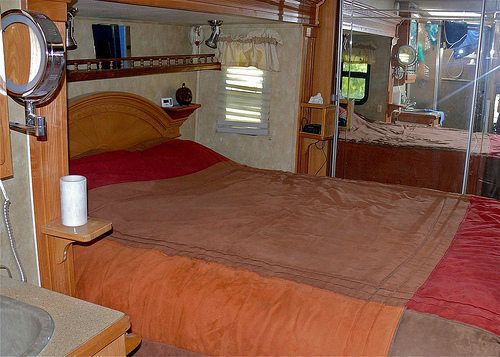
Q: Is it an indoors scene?
A: Yes, it is indoors.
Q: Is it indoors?
A: Yes, it is indoors.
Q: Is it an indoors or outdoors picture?
A: It is indoors.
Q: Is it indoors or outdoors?
A: It is indoors.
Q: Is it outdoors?
A: No, it is indoors.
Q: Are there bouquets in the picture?
A: No, there are no bouquets.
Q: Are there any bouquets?
A: No, there are no bouquets.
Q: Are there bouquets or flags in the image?
A: No, there are no bouquets or flags.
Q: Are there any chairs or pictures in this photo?
A: No, there are no chairs or pictures.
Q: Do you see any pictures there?
A: No, there are no pictures.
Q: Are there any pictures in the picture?
A: No, there are no pictures.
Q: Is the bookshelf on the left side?
A: Yes, the bookshelf is on the left of the image.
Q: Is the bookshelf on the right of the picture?
A: No, the bookshelf is on the left of the image.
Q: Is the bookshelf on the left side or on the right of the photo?
A: The bookshelf is on the left of the image.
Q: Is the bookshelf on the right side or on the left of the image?
A: The bookshelf is on the left of the image.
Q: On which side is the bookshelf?
A: The bookshelf is on the left of the image.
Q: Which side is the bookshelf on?
A: The bookshelf is on the left of the image.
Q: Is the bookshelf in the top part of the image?
A: Yes, the bookshelf is in the top of the image.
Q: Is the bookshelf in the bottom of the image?
A: No, the bookshelf is in the top of the image.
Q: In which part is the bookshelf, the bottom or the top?
A: The bookshelf is in the top of the image.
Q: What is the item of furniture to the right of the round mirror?
A: The piece of furniture is a bookshelf.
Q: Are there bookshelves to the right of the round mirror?
A: Yes, there is a bookshelf to the right of the mirror.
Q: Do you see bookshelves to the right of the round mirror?
A: Yes, there is a bookshelf to the right of the mirror.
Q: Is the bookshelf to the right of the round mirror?
A: Yes, the bookshelf is to the right of the mirror.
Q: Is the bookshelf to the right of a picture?
A: No, the bookshelf is to the right of the mirror.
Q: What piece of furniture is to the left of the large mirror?
A: The piece of furniture is a bookshelf.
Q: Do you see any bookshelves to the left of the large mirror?
A: Yes, there is a bookshelf to the left of the mirror.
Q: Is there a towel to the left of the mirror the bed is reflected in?
A: No, there is a bookshelf to the left of the mirror.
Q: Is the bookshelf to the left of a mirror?
A: Yes, the bookshelf is to the left of a mirror.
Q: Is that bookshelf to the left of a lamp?
A: No, the bookshelf is to the left of a mirror.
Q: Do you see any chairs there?
A: No, there are no chairs.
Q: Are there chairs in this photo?
A: No, there are no chairs.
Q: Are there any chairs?
A: No, there are no chairs.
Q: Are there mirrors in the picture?
A: Yes, there is a mirror.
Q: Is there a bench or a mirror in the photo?
A: Yes, there is a mirror.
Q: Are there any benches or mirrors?
A: Yes, there is a mirror.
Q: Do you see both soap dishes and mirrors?
A: No, there is a mirror but no soap dishes.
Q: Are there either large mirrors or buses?
A: Yes, there is a large mirror.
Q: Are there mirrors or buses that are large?
A: Yes, the mirror is large.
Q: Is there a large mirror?
A: Yes, there is a large mirror.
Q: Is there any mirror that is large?
A: Yes, there is a mirror that is large.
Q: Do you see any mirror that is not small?
A: Yes, there is a large mirror.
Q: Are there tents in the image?
A: No, there are no tents.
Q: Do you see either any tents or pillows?
A: No, there are no tents or pillows.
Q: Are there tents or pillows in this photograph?
A: No, there are no tents or pillows.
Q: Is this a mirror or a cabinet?
A: This is a mirror.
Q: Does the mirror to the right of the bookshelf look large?
A: Yes, the mirror is large.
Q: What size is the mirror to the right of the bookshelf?
A: The mirror is large.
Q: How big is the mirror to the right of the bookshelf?
A: The mirror is large.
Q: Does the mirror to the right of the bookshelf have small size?
A: No, the mirror is large.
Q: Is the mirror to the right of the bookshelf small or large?
A: The mirror is large.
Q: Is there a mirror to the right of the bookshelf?
A: Yes, there is a mirror to the right of the bookshelf.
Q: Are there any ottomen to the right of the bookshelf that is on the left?
A: No, there is a mirror to the right of the bookshelf.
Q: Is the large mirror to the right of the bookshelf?
A: Yes, the mirror is to the right of the bookshelf.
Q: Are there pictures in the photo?
A: No, there are no pictures.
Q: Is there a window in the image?
A: Yes, there is a window.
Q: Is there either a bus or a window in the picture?
A: Yes, there is a window.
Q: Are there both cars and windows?
A: No, there is a window but no cars.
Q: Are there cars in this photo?
A: No, there are no cars.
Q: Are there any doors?
A: Yes, there are doors.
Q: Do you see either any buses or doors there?
A: Yes, there are doors.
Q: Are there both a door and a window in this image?
A: Yes, there are both a door and a window.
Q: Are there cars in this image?
A: No, there are no cars.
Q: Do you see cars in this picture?
A: No, there are no cars.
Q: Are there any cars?
A: No, there are no cars.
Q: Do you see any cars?
A: No, there are no cars.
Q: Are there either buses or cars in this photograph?
A: No, there are no cars or buses.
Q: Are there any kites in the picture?
A: No, there are no kites.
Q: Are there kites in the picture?
A: No, there are no kites.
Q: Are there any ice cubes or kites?
A: No, there are no kites or ice cubes.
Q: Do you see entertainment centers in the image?
A: No, there are no entertainment centers.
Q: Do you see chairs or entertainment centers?
A: No, there are no entertainment centers or chairs.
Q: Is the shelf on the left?
A: Yes, the shelf is on the left of the image.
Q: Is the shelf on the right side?
A: No, the shelf is on the left of the image.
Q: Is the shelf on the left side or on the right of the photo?
A: The shelf is on the left of the image.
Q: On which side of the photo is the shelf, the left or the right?
A: The shelf is on the left of the image.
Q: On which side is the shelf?
A: The shelf is on the left of the image.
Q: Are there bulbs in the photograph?
A: No, there are no bulbs.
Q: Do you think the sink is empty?
A: Yes, the sink is empty.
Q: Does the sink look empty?
A: Yes, the sink is empty.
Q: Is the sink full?
A: No, the sink is empty.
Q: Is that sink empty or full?
A: The sink is empty.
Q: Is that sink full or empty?
A: The sink is empty.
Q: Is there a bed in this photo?
A: Yes, there is a bed.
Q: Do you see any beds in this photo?
A: Yes, there is a bed.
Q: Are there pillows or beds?
A: Yes, there is a bed.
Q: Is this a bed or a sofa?
A: This is a bed.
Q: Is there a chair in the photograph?
A: No, there are no chairs.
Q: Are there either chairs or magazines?
A: No, there are no chairs or magazines.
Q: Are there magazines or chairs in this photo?
A: No, there are no chairs or magazines.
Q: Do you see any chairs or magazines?
A: No, there are no chairs or magazines.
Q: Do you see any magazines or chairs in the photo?
A: No, there are no chairs or magazines.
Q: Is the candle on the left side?
A: Yes, the candle is on the left of the image.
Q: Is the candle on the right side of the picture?
A: No, the candle is on the left of the image.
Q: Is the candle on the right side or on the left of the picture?
A: The candle is on the left of the image.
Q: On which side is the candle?
A: The candle is on the left of the image.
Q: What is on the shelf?
A: The candle is on the shelf.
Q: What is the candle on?
A: The candle is on the shelf.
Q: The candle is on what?
A: The candle is on the shelf.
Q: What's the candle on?
A: The candle is on the shelf.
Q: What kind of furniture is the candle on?
A: The candle is on the shelf.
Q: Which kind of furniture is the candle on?
A: The candle is on the shelf.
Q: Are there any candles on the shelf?
A: Yes, there is a candle on the shelf.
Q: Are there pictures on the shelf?
A: No, there is a candle on the shelf.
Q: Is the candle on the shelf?
A: Yes, the candle is on the shelf.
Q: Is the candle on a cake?
A: No, the candle is on the shelf.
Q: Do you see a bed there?
A: Yes, there is a bed.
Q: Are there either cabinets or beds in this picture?
A: Yes, there is a bed.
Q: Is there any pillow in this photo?
A: No, there are no pillows.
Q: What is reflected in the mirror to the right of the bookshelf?
A: The bed is reflected in the mirror.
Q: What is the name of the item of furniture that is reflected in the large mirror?
A: The piece of furniture is a bed.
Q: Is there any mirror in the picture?
A: Yes, there is a mirror.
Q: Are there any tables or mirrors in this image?
A: Yes, there is a mirror.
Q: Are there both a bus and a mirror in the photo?
A: No, there is a mirror but no buses.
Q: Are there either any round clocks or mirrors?
A: Yes, there is a round mirror.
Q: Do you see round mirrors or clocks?
A: Yes, there is a round mirror.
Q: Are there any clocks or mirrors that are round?
A: Yes, the mirror is round.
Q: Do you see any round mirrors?
A: Yes, there is a round mirror.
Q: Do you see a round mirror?
A: Yes, there is a round mirror.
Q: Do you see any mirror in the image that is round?
A: Yes, there is a mirror that is round.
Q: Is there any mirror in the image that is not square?
A: Yes, there is a round mirror.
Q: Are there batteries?
A: No, there are no batteries.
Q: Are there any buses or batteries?
A: No, there are no batteries or buses.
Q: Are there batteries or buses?
A: No, there are no batteries or buses.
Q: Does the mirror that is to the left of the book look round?
A: Yes, the mirror is round.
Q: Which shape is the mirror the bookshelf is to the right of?
A: The mirror is round.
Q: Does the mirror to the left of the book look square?
A: No, the mirror is round.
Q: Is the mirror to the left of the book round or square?
A: The mirror is round.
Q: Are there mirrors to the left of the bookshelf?
A: Yes, there is a mirror to the left of the bookshelf.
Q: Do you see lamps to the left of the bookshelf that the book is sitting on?
A: No, there is a mirror to the left of the bookshelf.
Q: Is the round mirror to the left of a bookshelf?
A: Yes, the mirror is to the left of a bookshelf.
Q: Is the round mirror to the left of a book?
A: Yes, the mirror is to the left of a book.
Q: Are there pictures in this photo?
A: No, there are no pictures.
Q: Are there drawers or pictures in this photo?
A: No, there are no pictures or drawers.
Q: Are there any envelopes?
A: No, there are no envelopes.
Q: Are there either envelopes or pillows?
A: No, there are no envelopes or pillows.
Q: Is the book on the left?
A: Yes, the book is on the left of the image.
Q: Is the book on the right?
A: No, the book is on the left of the image.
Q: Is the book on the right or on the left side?
A: The book is on the left of the image.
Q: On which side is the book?
A: The book is on the left of the image.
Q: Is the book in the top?
A: Yes, the book is in the top of the image.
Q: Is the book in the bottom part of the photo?
A: No, the book is in the top of the image.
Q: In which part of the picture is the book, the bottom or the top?
A: The book is in the top of the image.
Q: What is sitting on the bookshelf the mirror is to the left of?
A: The book is sitting on the bookshelf.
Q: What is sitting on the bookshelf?
A: The book is sitting on the bookshelf.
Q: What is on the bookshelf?
A: The book is on the bookshelf.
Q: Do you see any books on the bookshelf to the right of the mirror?
A: Yes, there is a book on the bookshelf.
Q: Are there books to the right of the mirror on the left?
A: Yes, there is a book to the right of the mirror.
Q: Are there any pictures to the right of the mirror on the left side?
A: No, there is a book to the right of the mirror.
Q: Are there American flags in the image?
A: No, there are no American flags.